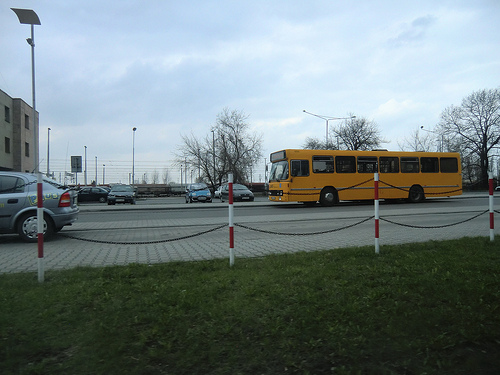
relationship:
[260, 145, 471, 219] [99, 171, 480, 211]
bus in parking lot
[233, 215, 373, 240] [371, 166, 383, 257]
chain draped between pole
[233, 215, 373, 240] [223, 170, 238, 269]
chain draped between pole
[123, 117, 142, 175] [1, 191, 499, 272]
lights in parking lot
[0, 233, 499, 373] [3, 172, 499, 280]
bushes on side of fence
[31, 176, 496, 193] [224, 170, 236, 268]
chain connecting post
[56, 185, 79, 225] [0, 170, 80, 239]
back end of car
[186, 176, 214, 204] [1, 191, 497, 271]
car in lot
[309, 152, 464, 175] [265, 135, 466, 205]
windows on bus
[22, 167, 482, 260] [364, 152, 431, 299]
chain on poles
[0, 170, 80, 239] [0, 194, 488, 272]
car on side of road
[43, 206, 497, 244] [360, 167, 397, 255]
chain on pole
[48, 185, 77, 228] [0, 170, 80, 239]
tail end of car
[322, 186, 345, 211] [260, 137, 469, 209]
wheel on bus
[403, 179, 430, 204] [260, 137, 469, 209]
wheel on bus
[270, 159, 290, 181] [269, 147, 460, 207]
windshield on bus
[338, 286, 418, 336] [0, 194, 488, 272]
green grass beside a road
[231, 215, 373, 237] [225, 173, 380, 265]
chain link between poles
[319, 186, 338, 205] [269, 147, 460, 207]
wheel of bus